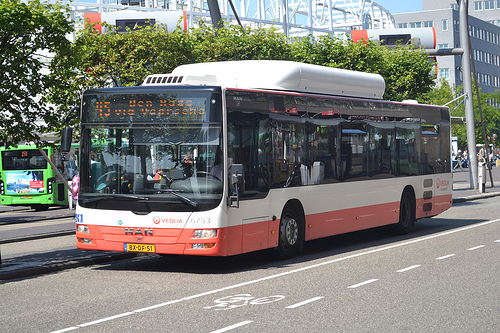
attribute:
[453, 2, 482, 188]
metal pole — large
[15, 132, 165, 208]
bus — large, green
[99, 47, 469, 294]
bus — white, orange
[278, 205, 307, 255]
bus wheel — round rubber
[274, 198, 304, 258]
bus wheel — round rubber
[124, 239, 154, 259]
license plate — black, red yellow 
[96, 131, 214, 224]
windshield wiper — black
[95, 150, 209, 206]
windshield wiper — black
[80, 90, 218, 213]
windshield — broad clear 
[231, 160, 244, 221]
mirror — black side, bus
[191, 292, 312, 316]
bike — white painted 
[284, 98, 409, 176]
window — bus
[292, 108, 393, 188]
window — bus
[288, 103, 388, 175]
window — bus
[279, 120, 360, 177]
window — bus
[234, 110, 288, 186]
window — bus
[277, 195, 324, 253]
tire — bus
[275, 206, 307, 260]
tire — bus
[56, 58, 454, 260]
bus — pinkish, white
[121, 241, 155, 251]
plate — yellow, rectangular